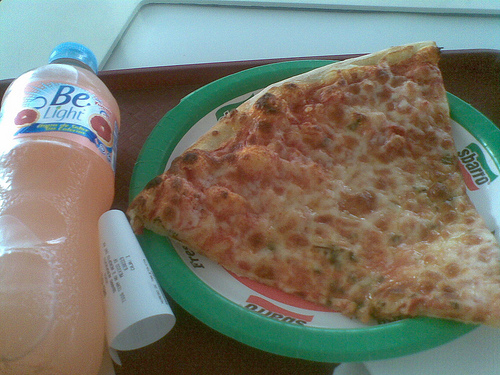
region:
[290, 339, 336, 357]
edge of a plate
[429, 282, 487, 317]
edge of a pizza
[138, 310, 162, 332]
edge of a receipt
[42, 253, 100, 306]
part of the bottle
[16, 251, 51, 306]
bubbles of the juice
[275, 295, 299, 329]
inner part of the plate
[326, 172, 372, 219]
surface of the pizza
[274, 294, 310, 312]
part of some writing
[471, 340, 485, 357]
part of some tissue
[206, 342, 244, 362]
part of the table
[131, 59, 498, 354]
green and white paper plate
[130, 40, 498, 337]
a piece of cheese pizza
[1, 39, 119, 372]
a plastic bottle of fruit juice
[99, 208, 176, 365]
a rolled up receipt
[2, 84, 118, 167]
label on drink bottle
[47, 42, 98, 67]
plastic cap of drink bottle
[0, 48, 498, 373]
brown plastic food tray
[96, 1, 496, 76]
a white table under tray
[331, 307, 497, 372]
paper napkin under plate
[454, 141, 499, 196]
restaurant name on plate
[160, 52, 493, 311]
Slice of pizza on a plate.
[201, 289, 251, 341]
The rim of the plate is green.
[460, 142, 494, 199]
Sbarro on the plate.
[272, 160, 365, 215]
Cheese on the pizza.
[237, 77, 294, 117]
Burnt spot on the crust.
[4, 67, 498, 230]
The food is on a tray.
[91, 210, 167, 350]
The receipt is white.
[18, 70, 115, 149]
Be light label on the bottle.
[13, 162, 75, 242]
The drink is pink.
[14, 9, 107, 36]
The table is white.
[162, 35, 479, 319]
slice of pizza on plate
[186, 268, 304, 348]
green border on paper plate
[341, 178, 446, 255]
melted cheese on top of pizza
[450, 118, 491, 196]
name of pizza restaurant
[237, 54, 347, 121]
crust of cooked pizza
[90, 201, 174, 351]
rolled up receipt paper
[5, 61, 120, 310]
beverage in plastic bottle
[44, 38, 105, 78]
blue plastic cape on bottle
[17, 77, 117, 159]
label on beverage bottle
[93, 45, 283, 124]
tray under bottle and plate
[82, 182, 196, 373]
Receipt by a plate.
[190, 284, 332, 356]
Black letters that say sbarro.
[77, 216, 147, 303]
Black letters on white paper.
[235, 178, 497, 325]
Cheese pizza with a green spice.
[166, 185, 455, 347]
Paper plate with pizza on it.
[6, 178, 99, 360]
A pink drink in a bottle.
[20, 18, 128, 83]
Blue cap on a plastic bottle.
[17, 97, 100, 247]
Drink that is called be light.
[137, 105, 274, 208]
Crispy brown crust of a pizza.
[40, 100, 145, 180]
Picture of a grape fruit.